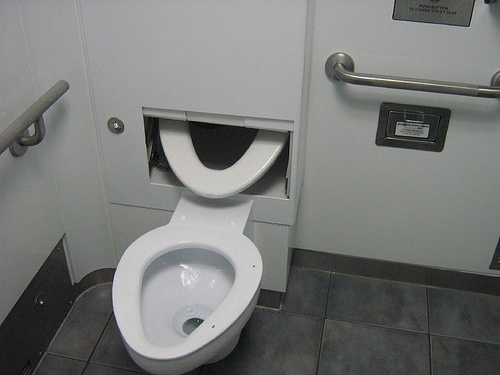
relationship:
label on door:
[394, 120, 430, 140] [386, 109, 440, 145]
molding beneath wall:
[296, 245, 499, 295] [300, 4, 499, 274]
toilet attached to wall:
[106, 195, 265, 371] [78, 3, 312, 305]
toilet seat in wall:
[157, 119, 292, 200] [78, 3, 312, 305]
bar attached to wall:
[1, 77, 74, 157] [0, 0, 75, 373]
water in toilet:
[170, 300, 217, 339] [106, 195, 265, 371]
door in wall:
[386, 109, 440, 145] [300, 4, 499, 274]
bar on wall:
[325, 52, 499, 104] [300, 4, 499, 274]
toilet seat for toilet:
[157, 119, 292, 200] [106, 195, 265, 371]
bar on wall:
[1, 77, 74, 157] [0, 0, 75, 373]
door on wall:
[386, 109, 440, 145] [300, 4, 499, 274]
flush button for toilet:
[106, 115, 126, 135] [106, 195, 265, 371]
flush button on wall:
[106, 115, 126, 135] [78, 3, 312, 305]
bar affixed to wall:
[325, 52, 499, 104] [300, 4, 499, 274]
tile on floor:
[324, 266, 433, 339] [36, 260, 499, 374]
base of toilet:
[206, 330, 244, 366] [106, 195, 265, 371]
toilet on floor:
[106, 195, 265, 371] [36, 260, 499, 374]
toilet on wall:
[106, 195, 265, 371] [78, 3, 312, 305]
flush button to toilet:
[106, 115, 126, 135] [106, 195, 265, 371]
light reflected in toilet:
[177, 259, 217, 289] [106, 195, 265, 371]